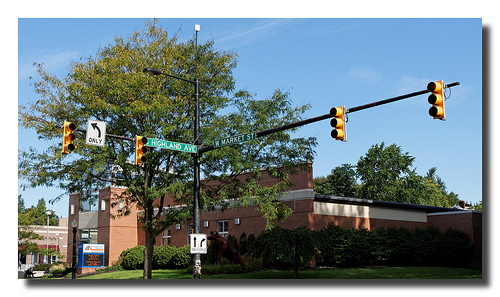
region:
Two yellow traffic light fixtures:
[329, 77, 446, 144]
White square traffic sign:
[187, 230, 209, 255]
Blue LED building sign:
[75, 240, 107, 267]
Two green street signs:
[138, 129, 255, 154]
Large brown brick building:
[59, 159, 484, 276]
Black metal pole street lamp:
[67, 215, 79, 278]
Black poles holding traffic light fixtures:
[59, 66, 459, 279]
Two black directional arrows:
[192, 233, 207, 248]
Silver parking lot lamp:
[45, 208, 52, 279]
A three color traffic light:
[63, 119, 77, 153]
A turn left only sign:
[84, 117, 106, 147]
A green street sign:
[212, 130, 258, 147]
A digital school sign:
[79, 241, 106, 268]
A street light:
[139, 65, 206, 275]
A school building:
[19, 161, 483, 271]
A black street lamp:
[69, 215, 79, 276]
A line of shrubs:
[118, 222, 476, 267]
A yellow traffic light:
[63, 130, 76, 141]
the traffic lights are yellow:
[331, 75, 477, 169]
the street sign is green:
[147, 136, 198, 155]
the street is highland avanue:
[150, 128, 220, 165]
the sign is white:
[83, 110, 112, 149]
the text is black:
[77, 110, 128, 153]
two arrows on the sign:
[185, 224, 217, 259]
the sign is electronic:
[79, 233, 114, 273]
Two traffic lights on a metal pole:
[40, 110, 161, 177]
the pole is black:
[175, 67, 220, 276]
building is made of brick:
[107, 157, 394, 262]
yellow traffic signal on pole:
[427, 77, 448, 135]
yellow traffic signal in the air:
[328, 106, 348, 146]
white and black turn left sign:
[83, 108, 118, 155]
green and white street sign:
[140, 135, 201, 158]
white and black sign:
[186, 230, 212, 257]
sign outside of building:
[83, 245, 121, 265]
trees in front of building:
[105, 47, 196, 118]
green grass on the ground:
[346, 269, 397, 285]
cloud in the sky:
[391, 82, 425, 111]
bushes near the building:
[121, 247, 189, 271]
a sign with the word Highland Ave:
[140, 137, 197, 157]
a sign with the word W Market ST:
[213, 129, 257, 146]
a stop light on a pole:
[328, 104, 350, 144]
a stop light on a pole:
[426, 77, 448, 121]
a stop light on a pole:
[59, 119, 79, 154]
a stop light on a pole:
[135, 132, 149, 164]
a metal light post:
[143, 64, 210, 281]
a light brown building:
[59, 158, 474, 280]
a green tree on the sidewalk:
[18, 18, 320, 288]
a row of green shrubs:
[121, 223, 477, 275]